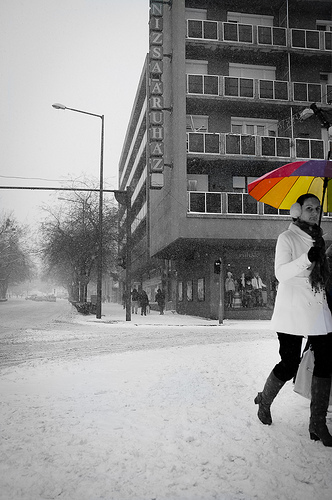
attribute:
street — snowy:
[2, 291, 331, 499]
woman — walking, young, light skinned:
[250, 192, 331, 450]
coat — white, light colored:
[266, 220, 331, 340]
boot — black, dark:
[251, 369, 287, 427]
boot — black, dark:
[306, 373, 331, 448]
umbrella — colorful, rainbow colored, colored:
[246, 156, 330, 268]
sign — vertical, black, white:
[142, 3, 168, 193]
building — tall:
[114, 1, 331, 326]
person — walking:
[154, 287, 168, 316]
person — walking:
[138, 288, 152, 317]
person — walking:
[130, 284, 139, 318]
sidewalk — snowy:
[68, 290, 273, 330]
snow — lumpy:
[2, 284, 327, 499]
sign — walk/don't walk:
[212, 256, 224, 277]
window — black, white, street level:
[221, 260, 279, 314]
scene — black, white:
[4, 3, 330, 497]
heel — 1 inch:
[252, 393, 263, 407]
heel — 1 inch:
[307, 431, 321, 443]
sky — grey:
[0, 3, 144, 278]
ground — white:
[2, 296, 331, 499]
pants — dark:
[270, 331, 331, 382]